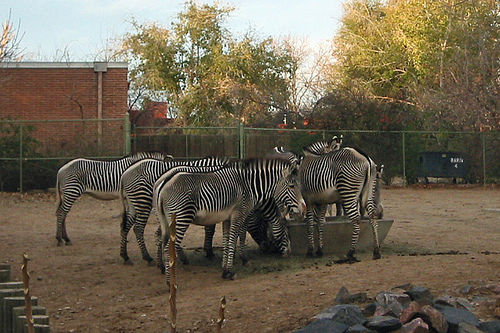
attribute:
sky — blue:
[49, 13, 96, 34]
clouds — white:
[250, 4, 307, 31]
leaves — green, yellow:
[344, 10, 438, 54]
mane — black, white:
[231, 161, 276, 178]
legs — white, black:
[164, 211, 239, 271]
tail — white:
[151, 181, 174, 250]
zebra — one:
[131, 158, 301, 271]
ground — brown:
[423, 207, 485, 245]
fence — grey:
[45, 123, 474, 155]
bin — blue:
[427, 142, 476, 184]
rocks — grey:
[318, 283, 430, 331]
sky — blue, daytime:
[3, 0, 349, 137]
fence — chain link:
[0, 109, 484, 192]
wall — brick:
[1, 59, 130, 181]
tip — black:
[120, 210, 128, 235]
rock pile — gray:
[297, 278, 497, 329]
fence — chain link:
[12, 103, 450, 202]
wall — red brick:
[18, 66, 142, 166]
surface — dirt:
[7, 196, 494, 310]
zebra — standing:
[156, 161, 308, 282]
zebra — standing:
[135, 155, 303, 278]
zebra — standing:
[116, 169, 266, 289]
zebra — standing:
[26, 139, 209, 250]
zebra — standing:
[270, 126, 381, 262]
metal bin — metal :
[275, 210, 392, 259]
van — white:
[318, 302, 406, 321]